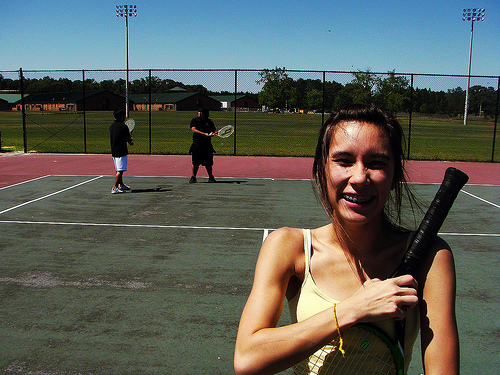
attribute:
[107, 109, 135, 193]
person — playing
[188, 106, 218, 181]
person — playing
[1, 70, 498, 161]
chain linked fence — black, tall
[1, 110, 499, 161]
grass — short, green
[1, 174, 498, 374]
court — green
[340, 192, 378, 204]
teeth — white